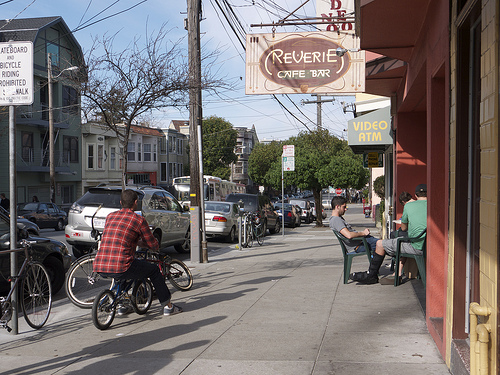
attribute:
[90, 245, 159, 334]
bicycle — small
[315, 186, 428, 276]
guys — sitting, together, outdoors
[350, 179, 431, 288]
man — sitting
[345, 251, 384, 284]
cast — black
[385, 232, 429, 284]
chair — green, patio chair, plastic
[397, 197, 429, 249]
shirt — plaid, green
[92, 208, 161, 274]
shirt — striped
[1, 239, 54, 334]
bicycle — parked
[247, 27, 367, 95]
sign — cafe bar, coffe shop sign, hanging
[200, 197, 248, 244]
car — parked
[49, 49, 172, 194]
tree — dead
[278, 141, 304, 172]
signs — parking signs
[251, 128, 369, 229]
tree — green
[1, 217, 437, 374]
sidewalk — gray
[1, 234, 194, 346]
bicycles — parked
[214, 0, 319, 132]
wires — hanging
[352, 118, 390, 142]
words — yellow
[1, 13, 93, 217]
building — four story